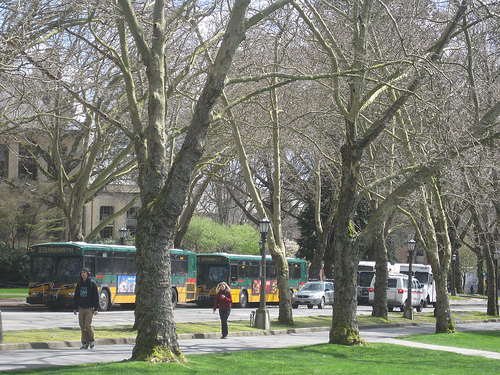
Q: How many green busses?
A: 2.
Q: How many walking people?
A: 2.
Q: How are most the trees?
A: Bald.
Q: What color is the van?
A: White.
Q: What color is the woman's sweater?
A: Red.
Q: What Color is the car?
A: Silver.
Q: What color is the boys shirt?
A: Black.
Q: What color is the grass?
A: Green.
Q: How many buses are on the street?
A: Two.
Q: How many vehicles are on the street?
A: There are several.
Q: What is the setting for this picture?
A: Suburban.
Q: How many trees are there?
A: There's a lot.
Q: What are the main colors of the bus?
A: Yellow and green.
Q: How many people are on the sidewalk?
A: Two.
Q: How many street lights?
A: Two.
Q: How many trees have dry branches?
A: All of them.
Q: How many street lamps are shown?
A: 4.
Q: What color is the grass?
A: Green.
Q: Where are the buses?
A: Parked on the curb.